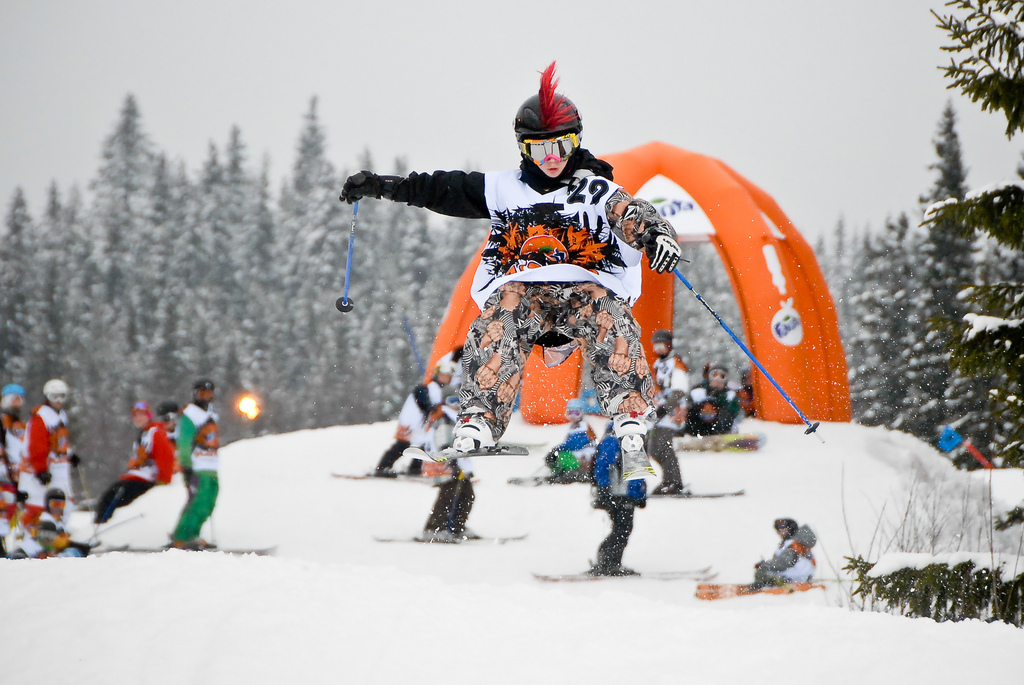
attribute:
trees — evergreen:
[26, 83, 493, 537]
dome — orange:
[656, 152, 896, 457]